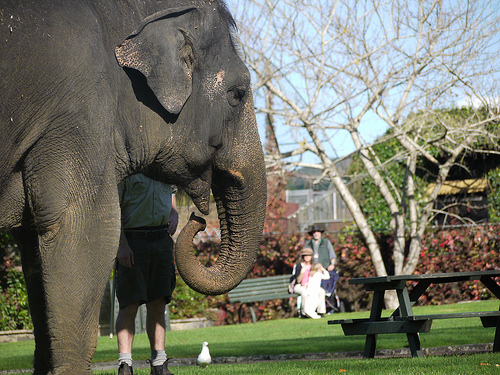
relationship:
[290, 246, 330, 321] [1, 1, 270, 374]
person looking at elephant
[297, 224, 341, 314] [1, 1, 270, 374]
person looking at elephant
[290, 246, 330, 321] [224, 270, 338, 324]
person sitting on a bench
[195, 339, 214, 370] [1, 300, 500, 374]
bird on ground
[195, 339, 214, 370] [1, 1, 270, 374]
bird near elephant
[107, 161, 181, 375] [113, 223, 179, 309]
man wearing shorts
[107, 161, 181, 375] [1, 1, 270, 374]
man standing by elephant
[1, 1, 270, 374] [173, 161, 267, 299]
elephant has trunk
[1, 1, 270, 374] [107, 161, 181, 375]
elephant next to man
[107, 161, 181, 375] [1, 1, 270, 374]
man near elephant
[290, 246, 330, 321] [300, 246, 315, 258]
person wearing a hat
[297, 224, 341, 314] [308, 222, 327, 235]
person wearing a hat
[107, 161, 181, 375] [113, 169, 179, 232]
man has shirt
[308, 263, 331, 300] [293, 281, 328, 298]
child on womans lap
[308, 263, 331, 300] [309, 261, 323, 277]
child has blonde hair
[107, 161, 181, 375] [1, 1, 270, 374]
man standing next to elephant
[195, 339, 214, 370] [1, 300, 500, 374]
bird standing on ground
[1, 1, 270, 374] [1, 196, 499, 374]
elephant in park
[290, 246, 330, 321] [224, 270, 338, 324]
person sitting on bench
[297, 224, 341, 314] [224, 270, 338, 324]
person standing behind bench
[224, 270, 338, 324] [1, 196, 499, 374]
bench in park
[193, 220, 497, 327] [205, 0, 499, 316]
bush behind tree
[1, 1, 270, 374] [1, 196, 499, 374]
elephant at park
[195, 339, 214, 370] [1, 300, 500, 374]
bird sits on ground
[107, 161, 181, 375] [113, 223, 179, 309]
man has shorts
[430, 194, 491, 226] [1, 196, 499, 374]
window overlooks park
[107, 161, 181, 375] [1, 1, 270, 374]
man standing behind a elephant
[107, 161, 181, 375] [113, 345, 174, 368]
man wearing socks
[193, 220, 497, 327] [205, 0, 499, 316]
bush next to tree